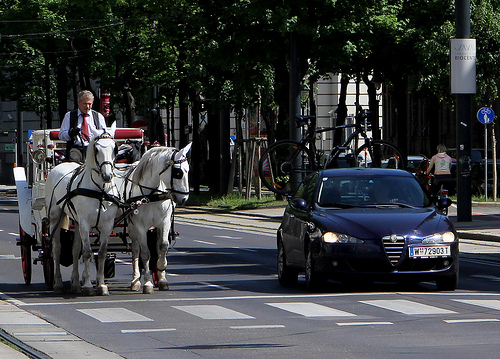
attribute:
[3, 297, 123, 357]
sidewalk — concrete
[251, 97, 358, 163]
bike — black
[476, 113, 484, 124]
road sign — blue, circular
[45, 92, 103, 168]
man — riding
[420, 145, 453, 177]
person — riding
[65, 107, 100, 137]
tie — red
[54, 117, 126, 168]
vest — black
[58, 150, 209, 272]
horses — pulling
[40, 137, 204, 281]
horses — white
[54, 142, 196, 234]
horses — white, pulling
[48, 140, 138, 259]
horse — white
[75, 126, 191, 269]
horse — white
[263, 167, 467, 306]
car — black, stopped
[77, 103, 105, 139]
tie — red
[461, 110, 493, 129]
sign — blue, white, round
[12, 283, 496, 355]
paint — white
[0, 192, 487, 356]
road — blue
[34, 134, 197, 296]
horses — white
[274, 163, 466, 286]
car — black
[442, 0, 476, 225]
posts — black